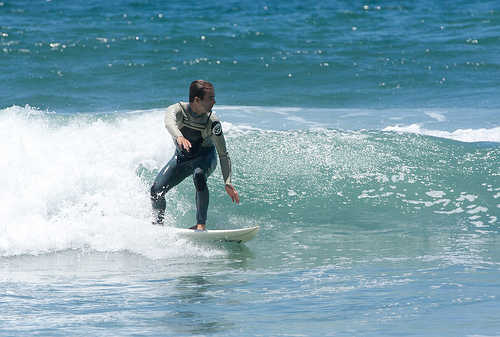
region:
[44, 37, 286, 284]
a man surfing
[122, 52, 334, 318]
a man in wet suit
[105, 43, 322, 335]
a man on a white surf board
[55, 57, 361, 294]
a man riding a wave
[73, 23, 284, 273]
a man that is wet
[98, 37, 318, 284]
a man in the ocean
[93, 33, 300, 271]
a man with wet hair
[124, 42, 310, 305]
a man during the day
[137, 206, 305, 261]
a white surfboard in the water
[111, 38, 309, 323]
a man leaning forward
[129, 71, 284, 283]
man on a surf board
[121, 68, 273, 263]
man with slicked back hair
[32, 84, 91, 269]
white foam on the ocean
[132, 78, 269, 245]
man in a wet suit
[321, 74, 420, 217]
sun light shining off the ocean water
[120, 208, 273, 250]
white surf board in the water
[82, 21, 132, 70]
waves in the ocean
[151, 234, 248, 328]
reflection of a surfer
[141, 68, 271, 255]
man surfing a small wave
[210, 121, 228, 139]
logo on the arm of a wet suit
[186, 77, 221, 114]
the head of a person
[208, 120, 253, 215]
the hand of a person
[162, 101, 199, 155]
the hand of a person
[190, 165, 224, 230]
the leg of a person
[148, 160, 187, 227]
the leg of a person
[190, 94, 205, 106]
the ear of a person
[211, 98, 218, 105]
the nose of a person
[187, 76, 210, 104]
the hair of a person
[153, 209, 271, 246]
a white surf board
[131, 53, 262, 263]
a person surfing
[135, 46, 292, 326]
a man surfing in the water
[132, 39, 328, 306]
a man surfing on a white surf board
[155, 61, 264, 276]
a man leaning on a surf board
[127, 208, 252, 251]
a white surf board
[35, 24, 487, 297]
body of blue water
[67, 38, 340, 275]
surfing during the day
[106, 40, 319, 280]
a man in a wet suit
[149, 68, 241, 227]
man in water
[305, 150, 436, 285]
blue water near man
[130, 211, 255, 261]
board under man's feet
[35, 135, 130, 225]
white waves in water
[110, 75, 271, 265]
man in a wetsuit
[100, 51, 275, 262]
man standing on white board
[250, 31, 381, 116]
calm water behind wave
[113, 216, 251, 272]
white surfboard in water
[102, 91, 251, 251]
blue and gray wetsuit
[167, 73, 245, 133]
man looking to his left